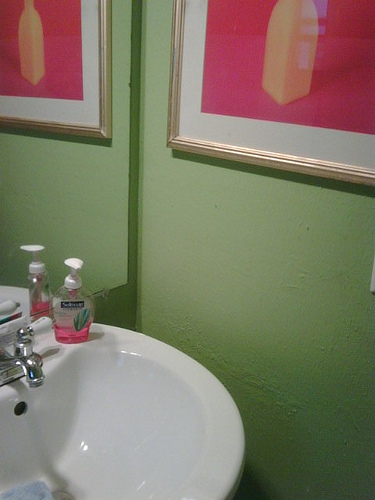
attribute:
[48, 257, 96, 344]
bottle — plastic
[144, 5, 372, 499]
wall — green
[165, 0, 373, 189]
frame — gold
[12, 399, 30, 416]
air hole — small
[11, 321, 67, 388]
faucet — metal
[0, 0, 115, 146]
image — mirrored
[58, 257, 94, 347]
bottle — transparent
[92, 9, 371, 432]
wall — green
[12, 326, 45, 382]
faucet — chrome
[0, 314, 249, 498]
bathroom sink — white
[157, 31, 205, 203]
frame — bronze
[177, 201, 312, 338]
wall — green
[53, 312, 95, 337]
soap — pink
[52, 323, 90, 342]
soap — pink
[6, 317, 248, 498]
sink — white, shiny, ceramic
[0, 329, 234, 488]
sink — small, white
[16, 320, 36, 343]
handle — white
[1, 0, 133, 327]
mirror — large